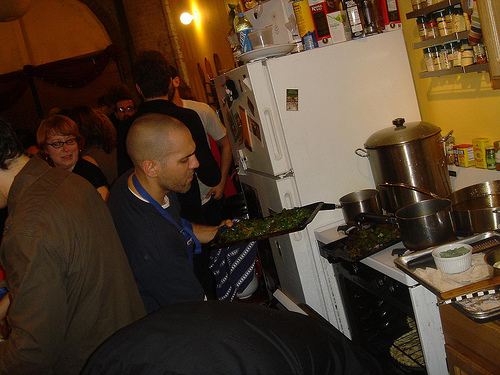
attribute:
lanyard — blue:
[129, 174, 204, 255]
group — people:
[1, 41, 256, 336]